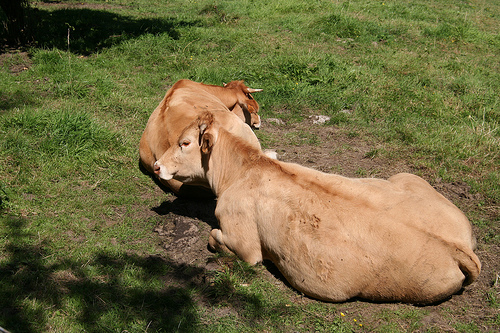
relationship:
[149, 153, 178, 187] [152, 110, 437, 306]
nose on cow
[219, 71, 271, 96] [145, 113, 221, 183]
horns on head